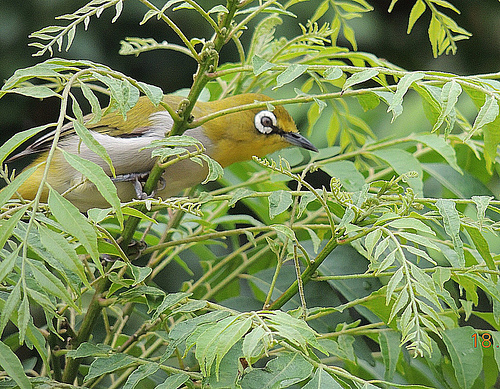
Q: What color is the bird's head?
A: Yellow.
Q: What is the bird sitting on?
A: A bush.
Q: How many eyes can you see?
A: One.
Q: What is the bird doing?
A: Perching on a branch.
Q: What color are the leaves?
A: Green.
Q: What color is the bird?
A: Yellow.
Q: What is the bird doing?
A: Hiding.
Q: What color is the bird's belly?
A: White.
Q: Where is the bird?
A: In a bush.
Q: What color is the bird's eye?
A: White.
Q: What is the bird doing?
A: Hiding.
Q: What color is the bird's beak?
A: Black.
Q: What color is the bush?
A: Green.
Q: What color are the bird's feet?
A: Black.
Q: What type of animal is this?
A: Bird.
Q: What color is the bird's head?
A: Yellow.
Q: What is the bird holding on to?
A: Branch.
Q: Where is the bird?
A: Hiding in a bush.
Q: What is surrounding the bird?
A: Green leaves.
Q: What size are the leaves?
A: Very small.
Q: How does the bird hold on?
A: With it's feet.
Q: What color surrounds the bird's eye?
A: White.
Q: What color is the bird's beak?
A: Black.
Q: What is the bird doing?
A: The bird is resting.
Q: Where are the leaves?
A: On the branch.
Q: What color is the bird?
A: The bird is yellow.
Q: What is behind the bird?
A: More trees.